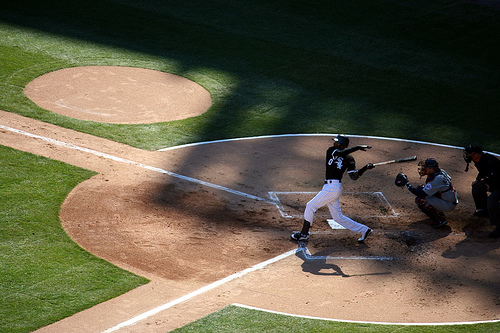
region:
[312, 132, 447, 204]
man is holding a bat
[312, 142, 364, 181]
the man is wearing a shirt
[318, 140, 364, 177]
the shirt is black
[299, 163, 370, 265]
man is wearing a trousers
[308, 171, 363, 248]
the trouser is white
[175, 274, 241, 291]
the line is on the ground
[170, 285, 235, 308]
the line is white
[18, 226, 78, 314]
the grass is green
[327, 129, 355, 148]
man is wearing a helmet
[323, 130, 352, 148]
the helmet is black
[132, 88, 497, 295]
A baseball game.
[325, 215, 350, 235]
Home plate.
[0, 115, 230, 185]
A line of white chalk in the dirt.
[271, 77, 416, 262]
The baseball player is holding a bat in his left hand.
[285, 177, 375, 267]
The batter's pants are white.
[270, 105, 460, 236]
The catcher is crouching behind the batter.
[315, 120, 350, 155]
The batter is wearing a helmet.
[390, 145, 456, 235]
The catcher is wearing a protective mask.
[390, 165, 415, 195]
The catcher is wearing a glove.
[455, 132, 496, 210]
The umpire.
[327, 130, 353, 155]
Man is wearing helmet.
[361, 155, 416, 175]
Man is holding baseball bat.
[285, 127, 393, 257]
Man is standing on home base.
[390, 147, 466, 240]
Catcher is crouched behind batter.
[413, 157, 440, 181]
Catcher is wearing face guard.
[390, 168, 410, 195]
Catcher is wearing baseball mitt.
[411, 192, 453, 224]
Catcher is wearing shin guards.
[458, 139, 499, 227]
Umpire is crouched behind Catcher.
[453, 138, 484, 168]
Umpire is wearing face guard.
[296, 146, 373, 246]
Batter is wearing baseball uniform.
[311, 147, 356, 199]
Man wearing black shirt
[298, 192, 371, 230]
Man wearing white pants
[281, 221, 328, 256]
Man's shoes are white and black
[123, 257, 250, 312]
White lines on baseball field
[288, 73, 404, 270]
Man is swinging bat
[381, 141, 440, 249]
Catcher is crouched down behind batter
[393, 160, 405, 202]
Mitt in left hand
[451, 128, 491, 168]
Umpire behind catcher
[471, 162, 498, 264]
Umpire wearing black clothes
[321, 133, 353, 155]
Batter wearing black helmet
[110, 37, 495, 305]
Men playing baseball game.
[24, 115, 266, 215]
White lines painted in dirt.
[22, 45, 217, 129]
A round dirt circle.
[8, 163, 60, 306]
Green grass on baseball field.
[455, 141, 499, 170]
Protective covering on umpire's face.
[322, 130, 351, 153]
Safety helmet on batter.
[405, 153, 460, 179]
Protective covering on catcher's face.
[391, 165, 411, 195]
Catcher's mitt on left hand.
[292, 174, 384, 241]
White baseball uniform pants.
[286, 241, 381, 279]
Shadow of batter.